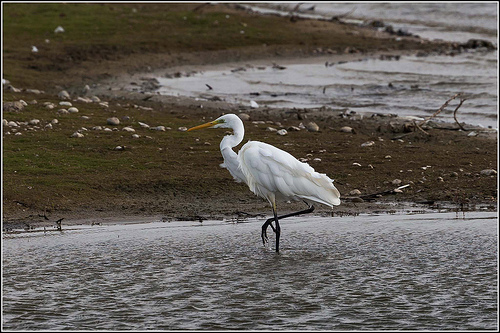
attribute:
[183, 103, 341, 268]
bird — white, standing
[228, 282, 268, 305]
water — brown, dark, flowing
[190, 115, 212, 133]
bill — yellow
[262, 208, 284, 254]
leg — brown, black, bent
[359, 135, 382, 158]
rocks — brown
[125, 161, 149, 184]
grass — brown, green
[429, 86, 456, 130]
branch — brown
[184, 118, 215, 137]
beak — yellow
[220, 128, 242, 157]
neck — long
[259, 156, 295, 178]
feathers — white